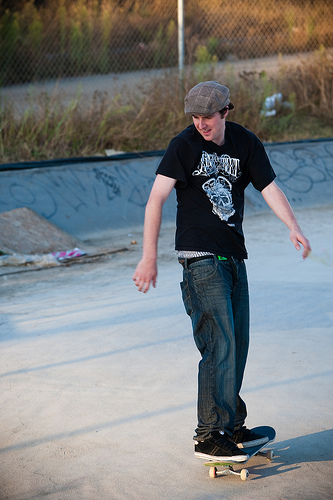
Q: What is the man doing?
A: Skateboarding.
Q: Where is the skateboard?
A: Under the man.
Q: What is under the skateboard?
A: Wheels.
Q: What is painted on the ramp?
A: Graffiti.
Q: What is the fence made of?
A: Chain link.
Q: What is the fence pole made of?
A: Metal.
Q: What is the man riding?
A: Skateboard.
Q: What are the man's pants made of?
A: Denim.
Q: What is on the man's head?
A: A hat.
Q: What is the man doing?
A: Riding a skateboard.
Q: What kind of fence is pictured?
A: Chain-link.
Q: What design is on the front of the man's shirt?
A: A skull.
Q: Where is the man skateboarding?
A: In a skate park.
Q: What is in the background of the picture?
A: Trees.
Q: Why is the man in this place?
A: To ride a skateboard.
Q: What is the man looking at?
A: The ground.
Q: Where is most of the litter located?
A: The roadside.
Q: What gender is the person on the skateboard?
A: Male.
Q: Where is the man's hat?
A: On his head.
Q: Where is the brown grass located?
A: By the roadside.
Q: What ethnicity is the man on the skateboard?
A: Caucasian.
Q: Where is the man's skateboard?
A: Under his feet.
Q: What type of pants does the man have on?
A: Jeans.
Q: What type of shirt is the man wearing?
A: Tshirt.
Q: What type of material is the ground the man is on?
A: Concrete.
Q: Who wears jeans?
A: The boy.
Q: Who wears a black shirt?
A: The boy.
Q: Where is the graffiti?
A: In the skate park.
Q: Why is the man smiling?
A: He is happy.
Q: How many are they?
A: 1.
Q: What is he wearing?
A: Sneakers.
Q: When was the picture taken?
A: During the day.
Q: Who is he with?
A: No one.